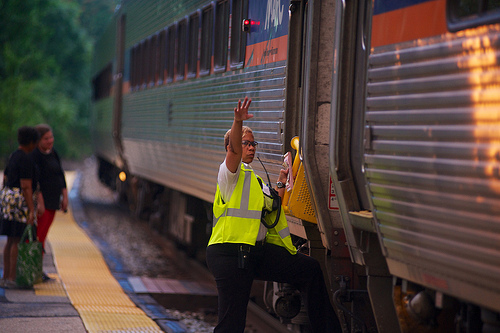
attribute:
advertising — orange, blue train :
[241, 4, 290, 69]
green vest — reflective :
[203, 157, 302, 257]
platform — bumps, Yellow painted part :
[53, 246, 159, 331]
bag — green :
[16, 222, 42, 290]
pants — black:
[202, 239, 333, 326]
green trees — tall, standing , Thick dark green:
[0, 1, 110, 166]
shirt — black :
[39, 150, 67, 210]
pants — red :
[37, 210, 55, 243]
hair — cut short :
[223, 127, 252, 148]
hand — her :
[231, 93, 257, 120]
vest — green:
[191, 157, 312, 257]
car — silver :
[120, 2, 315, 272]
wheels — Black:
[118, 179, 203, 234]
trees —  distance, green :
[3, 5, 93, 157]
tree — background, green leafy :
[1, 14, 87, 139]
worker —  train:
[205, 95, 304, 330]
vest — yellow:
[205, 160, 297, 260]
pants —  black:
[200, 238, 258, 321]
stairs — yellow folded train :
[274, 119, 323, 250]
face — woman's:
[234, 128, 260, 167]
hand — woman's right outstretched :
[218, 91, 257, 188]